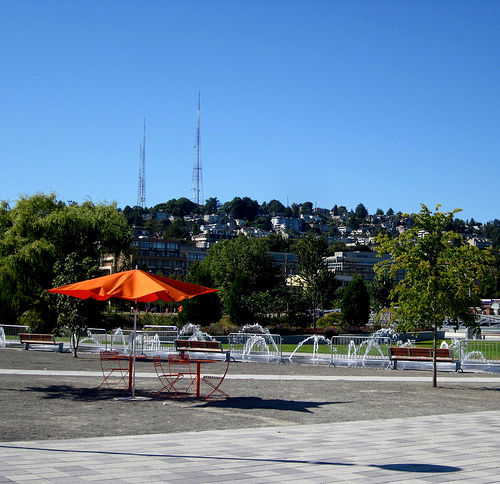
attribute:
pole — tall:
[162, 73, 226, 213]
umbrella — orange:
[43, 255, 221, 301]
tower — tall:
[188, 88, 205, 183]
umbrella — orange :
[44, 263, 221, 303]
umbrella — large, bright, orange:
[45, 266, 220, 399]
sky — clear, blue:
[8, 7, 493, 203]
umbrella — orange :
[46, 268, 213, 303]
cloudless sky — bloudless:
[1, 1, 499, 226]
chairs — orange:
[146, 352, 191, 397]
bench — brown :
[16, 331, 67, 356]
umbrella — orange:
[48, 268, 212, 307]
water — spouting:
[260, 330, 371, 370]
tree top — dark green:
[376, 204, 497, 331]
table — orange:
[102, 330, 279, 429]